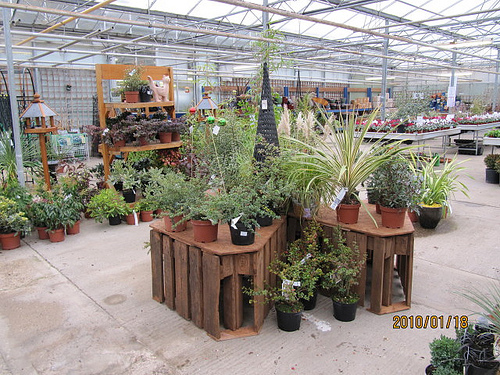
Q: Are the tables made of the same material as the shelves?
A: Yes, both the tables and the shelves are made of wood.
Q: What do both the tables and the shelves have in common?
A: The material, both the tables and the shelves are wooden.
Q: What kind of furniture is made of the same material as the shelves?
A: The tables are made of the same material as the shelves.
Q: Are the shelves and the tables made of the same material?
A: Yes, both the shelves and the tables are made of wood.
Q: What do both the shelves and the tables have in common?
A: The material, both the shelves and the tables are wooden.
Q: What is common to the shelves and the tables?
A: The material, both the shelves and the tables are wooden.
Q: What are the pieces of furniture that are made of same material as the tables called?
A: The pieces of furniture are shelves.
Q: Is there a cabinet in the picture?
A: No, there are no cabinets.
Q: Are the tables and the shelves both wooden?
A: Yes, both the tables and the shelves are wooden.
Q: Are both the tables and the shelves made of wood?
A: Yes, both the tables and the shelves are made of wood.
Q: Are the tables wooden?
A: Yes, the tables are wooden.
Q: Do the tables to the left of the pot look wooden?
A: Yes, the tables are wooden.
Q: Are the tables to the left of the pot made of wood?
A: Yes, the tables are made of wood.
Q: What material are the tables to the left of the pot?
A: The tables are made of wood.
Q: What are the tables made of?
A: The tables are made of wood.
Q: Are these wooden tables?
A: Yes, these are wooden tables.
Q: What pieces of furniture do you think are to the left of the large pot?
A: The pieces of furniture are tables.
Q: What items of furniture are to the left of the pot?
A: The pieces of furniture are tables.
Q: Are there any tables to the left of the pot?
A: Yes, there are tables to the left of the pot.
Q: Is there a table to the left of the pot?
A: Yes, there are tables to the left of the pot.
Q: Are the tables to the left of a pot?
A: Yes, the tables are to the left of a pot.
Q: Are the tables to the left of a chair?
A: No, the tables are to the left of a pot.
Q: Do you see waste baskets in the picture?
A: No, there are no waste baskets.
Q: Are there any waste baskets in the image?
A: No, there are no waste baskets.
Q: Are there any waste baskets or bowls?
A: No, there are no waste baskets or bowls.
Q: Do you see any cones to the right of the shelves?
A: Yes, there are cones to the right of the shelves.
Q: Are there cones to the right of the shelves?
A: Yes, there are cones to the right of the shelves.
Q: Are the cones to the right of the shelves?
A: Yes, the cones are to the right of the shelves.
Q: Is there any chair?
A: No, there are no chairs.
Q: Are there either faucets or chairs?
A: No, there are no chairs or faucets.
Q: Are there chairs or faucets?
A: No, there are no chairs or faucets.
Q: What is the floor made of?
A: The floor is made of concrete.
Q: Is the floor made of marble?
A: No, the floor is made of concrete.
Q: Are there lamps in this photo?
A: No, there are no lamps.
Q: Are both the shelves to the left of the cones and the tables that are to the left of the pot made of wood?
A: Yes, both the shelves and the tables are made of wood.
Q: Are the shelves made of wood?
A: Yes, the shelves are made of wood.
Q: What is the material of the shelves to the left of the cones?
A: The shelves are made of wood.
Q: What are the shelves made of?
A: The shelves are made of wood.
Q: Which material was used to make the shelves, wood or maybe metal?
A: The shelves are made of wood.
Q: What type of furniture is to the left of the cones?
A: The pieces of furniture are shelves.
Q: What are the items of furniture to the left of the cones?
A: The pieces of furniture are shelves.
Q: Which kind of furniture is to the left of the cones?
A: The pieces of furniture are shelves.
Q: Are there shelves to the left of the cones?
A: Yes, there are shelves to the left of the cones.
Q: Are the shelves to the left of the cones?
A: Yes, the shelves are to the left of the cones.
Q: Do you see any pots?
A: Yes, there is a pot.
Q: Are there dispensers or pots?
A: Yes, there is a pot.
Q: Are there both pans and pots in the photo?
A: No, there is a pot but no pans.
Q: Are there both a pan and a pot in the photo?
A: No, there is a pot but no pans.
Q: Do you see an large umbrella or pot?
A: Yes, there is a large pot.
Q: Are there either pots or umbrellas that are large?
A: Yes, the pot is large.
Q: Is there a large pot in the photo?
A: Yes, there is a large pot.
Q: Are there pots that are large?
A: Yes, there is a pot that is large.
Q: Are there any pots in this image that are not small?
A: Yes, there is a large pot.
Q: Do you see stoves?
A: No, there are no stoves.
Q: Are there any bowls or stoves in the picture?
A: No, there are no stoves or bowls.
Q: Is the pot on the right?
A: Yes, the pot is on the right of the image.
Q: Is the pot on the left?
A: No, the pot is on the right of the image.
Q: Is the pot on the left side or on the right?
A: The pot is on the right of the image.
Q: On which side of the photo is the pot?
A: The pot is on the right of the image.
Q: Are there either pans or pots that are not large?
A: No, there is a pot but it is large.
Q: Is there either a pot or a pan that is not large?
A: No, there is a pot but it is large.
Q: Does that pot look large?
A: Yes, the pot is large.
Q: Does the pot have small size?
A: No, the pot is large.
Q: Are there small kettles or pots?
A: No, there is a pot but it is large.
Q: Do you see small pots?
A: No, there is a pot but it is large.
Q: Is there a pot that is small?
A: No, there is a pot but it is large.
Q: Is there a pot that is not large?
A: No, there is a pot but it is large.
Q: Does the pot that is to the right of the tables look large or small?
A: The pot is large.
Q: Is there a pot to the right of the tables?
A: Yes, there is a pot to the right of the tables.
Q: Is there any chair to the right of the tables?
A: No, there is a pot to the right of the tables.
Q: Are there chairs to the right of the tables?
A: No, there is a pot to the right of the tables.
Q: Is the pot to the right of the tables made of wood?
A: Yes, the pot is to the right of the tables.